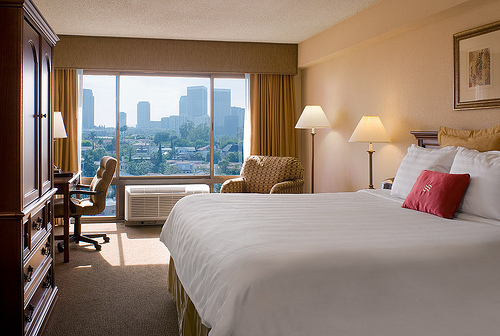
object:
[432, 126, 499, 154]
pillow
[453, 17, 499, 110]
art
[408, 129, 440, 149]
headboard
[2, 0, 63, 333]
armoire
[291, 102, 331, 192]
lamp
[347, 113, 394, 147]
shade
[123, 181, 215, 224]
air conditioner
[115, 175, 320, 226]
wall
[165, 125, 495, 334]
bed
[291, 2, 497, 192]
wall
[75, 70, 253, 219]
window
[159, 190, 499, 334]
sheet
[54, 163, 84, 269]
desk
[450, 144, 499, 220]
pillow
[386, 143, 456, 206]
pillow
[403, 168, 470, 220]
pillow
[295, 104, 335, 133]
shade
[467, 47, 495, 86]
picture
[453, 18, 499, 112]
frame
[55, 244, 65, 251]
wheel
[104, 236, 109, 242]
wheel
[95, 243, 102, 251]
wheel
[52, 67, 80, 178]
curtain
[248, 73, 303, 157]
curtain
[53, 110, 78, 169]
lamp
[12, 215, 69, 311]
furniture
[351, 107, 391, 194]
lamp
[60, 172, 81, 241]
lamp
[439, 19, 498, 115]
picture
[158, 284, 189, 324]
bed skirt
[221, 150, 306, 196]
chair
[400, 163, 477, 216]
red item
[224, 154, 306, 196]
beige item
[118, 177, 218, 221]
item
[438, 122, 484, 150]
item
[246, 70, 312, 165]
item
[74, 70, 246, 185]
item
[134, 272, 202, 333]
brown area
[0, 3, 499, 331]
hotel room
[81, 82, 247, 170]
skyline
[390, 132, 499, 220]
pillows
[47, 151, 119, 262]
chair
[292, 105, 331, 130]
floor lamps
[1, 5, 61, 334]
dresser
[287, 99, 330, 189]
light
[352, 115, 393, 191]
lights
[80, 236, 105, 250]
legs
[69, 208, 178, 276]
light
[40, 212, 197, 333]
carpet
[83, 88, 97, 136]
buildings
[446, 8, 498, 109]
painting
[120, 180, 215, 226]
radiator